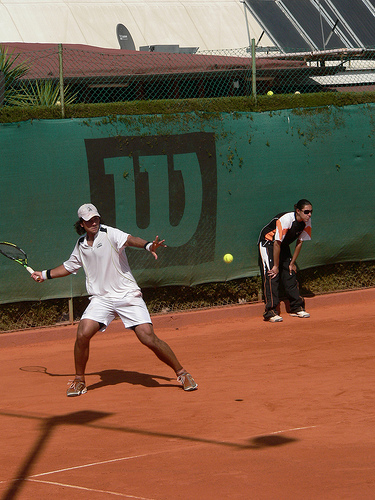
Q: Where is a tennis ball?
A: In the air.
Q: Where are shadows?
A: On the court.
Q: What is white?
A: Hat.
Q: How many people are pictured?
A: Two.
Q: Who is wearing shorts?
A: Tennis player.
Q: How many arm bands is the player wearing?
A: Two.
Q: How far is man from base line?
A: Feet away.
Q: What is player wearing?
A: Tennis whites.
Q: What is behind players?
A: Fence for tennis courts.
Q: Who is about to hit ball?
A: Tennis player.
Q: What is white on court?
A: Paint.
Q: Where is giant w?
A: On fence.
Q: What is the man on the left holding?
A: A tennis racket.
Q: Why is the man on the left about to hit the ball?
A: He's a tennis player.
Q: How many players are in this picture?
A: One.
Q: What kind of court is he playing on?
A: Clay.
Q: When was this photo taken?
A: During the day.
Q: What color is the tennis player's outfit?
A: White.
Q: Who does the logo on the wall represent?
A: Wilson.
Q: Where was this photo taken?
A: A tennis court.